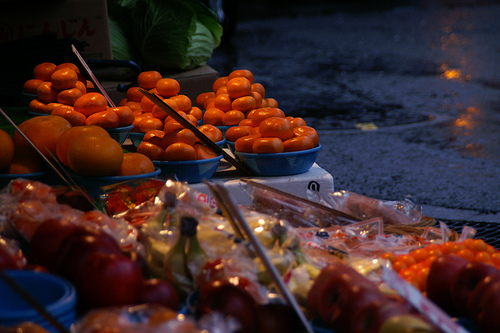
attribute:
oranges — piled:
[0, 124, 106, 182]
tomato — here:
[17, 114, 73, 153]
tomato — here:
[49, 66, 79, 92]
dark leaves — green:
[109, 2, 226, 69]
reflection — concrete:
[337, 3, 498, 190]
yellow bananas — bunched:
[134, 194, 322, 266]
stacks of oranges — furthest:
[24, 62, 279, 113]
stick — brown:
[237, 178, 364, 226]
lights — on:
[0, 0, 497, 331]